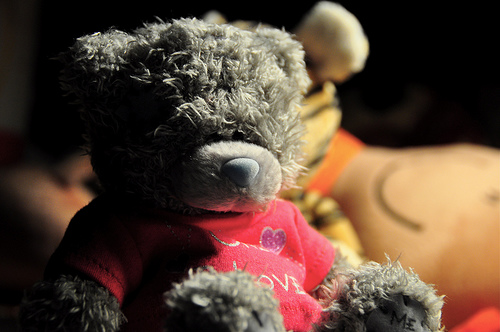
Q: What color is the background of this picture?
A: Black.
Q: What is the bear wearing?
A: A t-shirt.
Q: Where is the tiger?
A: Behind the bear.